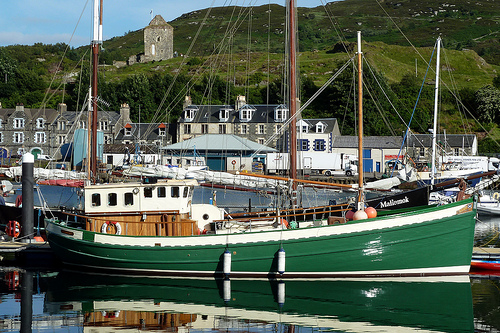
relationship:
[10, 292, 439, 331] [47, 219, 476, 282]
reflection of boat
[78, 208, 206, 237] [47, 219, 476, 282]
housing on top of boat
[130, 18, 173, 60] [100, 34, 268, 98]
castle on top of hill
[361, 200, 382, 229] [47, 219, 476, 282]
ball on top of boat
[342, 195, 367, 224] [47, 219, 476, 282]
ball on top of boat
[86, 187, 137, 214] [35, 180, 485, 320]
windows are on top of boat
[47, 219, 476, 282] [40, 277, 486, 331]
boat reflected in water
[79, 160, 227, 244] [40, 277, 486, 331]
cabin reflected in water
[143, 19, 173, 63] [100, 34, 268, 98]
buildings on side of hill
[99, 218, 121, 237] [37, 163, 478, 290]
life buoy hanging on fishing boat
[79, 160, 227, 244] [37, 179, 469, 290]
cabin on fishing boat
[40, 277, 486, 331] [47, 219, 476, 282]
water full of boat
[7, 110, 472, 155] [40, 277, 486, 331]
building beside water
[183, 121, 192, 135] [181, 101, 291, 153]
window in building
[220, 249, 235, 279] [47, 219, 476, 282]
weight attached to boat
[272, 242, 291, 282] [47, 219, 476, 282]
weight attached to boat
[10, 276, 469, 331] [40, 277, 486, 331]
reflection on top ofto water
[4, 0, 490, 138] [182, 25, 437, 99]
mountain background covered in greenery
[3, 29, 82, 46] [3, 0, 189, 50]
clouds in sky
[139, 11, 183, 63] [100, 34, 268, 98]
structure on hill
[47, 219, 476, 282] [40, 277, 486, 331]
boat on water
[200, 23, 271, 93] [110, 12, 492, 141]
grass covering surface